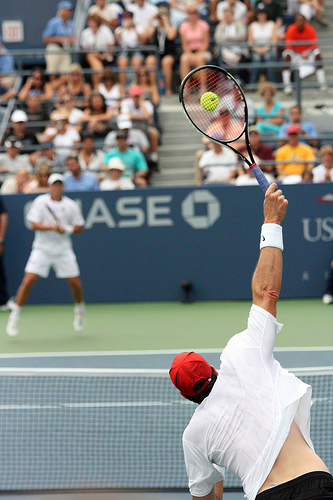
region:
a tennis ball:
[200, 93, 213, 109]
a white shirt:
[209, 384, 272, 432]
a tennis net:
[57, 377, 139, 459]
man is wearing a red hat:
[161, 358, 210, 380]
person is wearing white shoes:
[7, 306, 107, 332]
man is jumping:
[27, 178, 118, 335]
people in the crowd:
[29, 94, 173, 183]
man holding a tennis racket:
[171, 77, 286, 196]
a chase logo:
[97, 198, 244, 230]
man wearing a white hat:
[46, 173, 65, 185]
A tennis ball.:
[196, 89, 222, 111]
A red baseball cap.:
[165, 350, 217, 399]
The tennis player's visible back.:
[253, 397, 331, 497]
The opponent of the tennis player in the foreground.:
[4, 168, 98, 342]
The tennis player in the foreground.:
[163, 175, 332, 498]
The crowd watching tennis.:
[0, 0, 331, 193]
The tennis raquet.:
[172, 60, 277, 205]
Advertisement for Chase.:
[19, 186, 223, 235]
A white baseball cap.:
[46, 172, 68, 185]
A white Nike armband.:
[258, 221, 288, 252]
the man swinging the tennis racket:
[162, 58, 306, 497]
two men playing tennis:
[37, 72, 322, 482]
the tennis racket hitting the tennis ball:
[177, 58, 294, 236]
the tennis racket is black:
[152, 54, 296, 224]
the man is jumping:
[1, 159, 97, 343]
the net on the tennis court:
[4, 377, 275, 497]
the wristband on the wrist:
[254, 213, 295, 264]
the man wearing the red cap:
[137, 349, 288, 470]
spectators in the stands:
[37, 41, 330, 158]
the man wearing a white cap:
[42, 157, 81, 212]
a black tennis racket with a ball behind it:
[166, 50, 275, 204]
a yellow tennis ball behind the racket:
[197, 84, 242, 133]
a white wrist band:
[252, 213, 287, 260]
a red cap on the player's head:
[147, 346, 217, 388]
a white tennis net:
[24, 356, 145, 455]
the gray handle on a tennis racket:
[245, 154, 269, 198]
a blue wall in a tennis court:
[89, 190, 256, 298]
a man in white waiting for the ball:
[12, 161, 98, 332]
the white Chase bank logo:
[181, 189, 222, 233]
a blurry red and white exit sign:
[3, 10, 25, 44]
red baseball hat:
[142, 348, 218, 405]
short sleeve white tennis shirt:
[169, 305, 315, 499]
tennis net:
[5, 361, 173, 499]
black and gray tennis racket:
[163, 58, 271, 196]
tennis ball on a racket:
[193, 85, 219, 115]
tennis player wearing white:
[8, 161, 95, 342]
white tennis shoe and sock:
[64, 294, 87, 333]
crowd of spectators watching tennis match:
[2, 2, 165, 171]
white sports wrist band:
[250, 214, 289, 257]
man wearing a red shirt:
[281, 7, 331, 97]